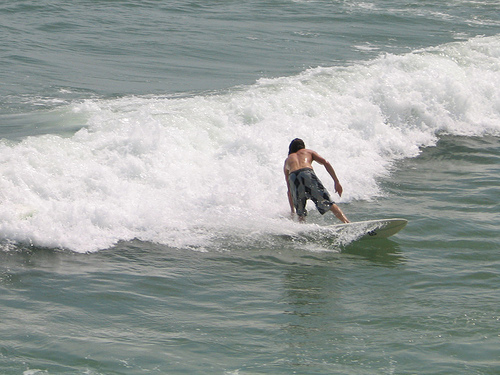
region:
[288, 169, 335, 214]
shorts on man's body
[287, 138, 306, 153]
hair on man's head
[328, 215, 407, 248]
surfboard under man's body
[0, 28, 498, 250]
wave rolling in in water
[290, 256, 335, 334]
shadow of man in water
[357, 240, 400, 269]
shadow of surfboard in water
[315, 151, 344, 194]
arm on man's body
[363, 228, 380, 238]
logo on bottom of surfboard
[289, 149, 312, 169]
back of man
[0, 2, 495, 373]
water of the ocean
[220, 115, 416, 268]
person surfing the waves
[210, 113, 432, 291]
male person surfing the waves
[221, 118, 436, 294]
guy surfing the waves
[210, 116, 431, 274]
person surfing ocean waves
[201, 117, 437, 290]
person surfing the nice waves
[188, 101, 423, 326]
person surfing the awesome waves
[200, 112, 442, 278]
person surfing the good waves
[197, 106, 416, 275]
person surfing some nice waves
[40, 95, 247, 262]
some strong ocean waves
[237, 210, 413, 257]
surfboard in the ocean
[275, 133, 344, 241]
surfer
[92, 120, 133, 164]
white and gray ocean waves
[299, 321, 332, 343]
white and gray ocean waves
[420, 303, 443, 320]
white and gray ocean waves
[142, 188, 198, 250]
white and gray ocean waves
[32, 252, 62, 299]
white and gray ocean waves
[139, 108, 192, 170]
white and gray ocean waves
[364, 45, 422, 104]
white and gray ocean waves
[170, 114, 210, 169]
white and gray ocean waves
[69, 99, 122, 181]
white and gray ocean waves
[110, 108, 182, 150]
waves in white and gray ocean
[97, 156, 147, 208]
waves in white and gray ocean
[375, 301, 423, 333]
waves in white and gray ocean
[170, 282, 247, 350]
waves in white and gray ocean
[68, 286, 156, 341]
waves in white and gray ocean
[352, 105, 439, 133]
waves in white and gray ocean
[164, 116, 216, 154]
waves in white and gray ocean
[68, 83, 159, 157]
waves in white and gray ocean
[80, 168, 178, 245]
waves in white and gray ocean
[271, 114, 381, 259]
Man in the water.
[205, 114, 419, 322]
Man on a surfboard.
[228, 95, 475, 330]
Man wearing swim trunks.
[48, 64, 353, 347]
Waves in the ocean.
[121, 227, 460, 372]
Ripples in the water.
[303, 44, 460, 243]
Spray on the ocean.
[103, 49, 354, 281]
White caps on the waves.